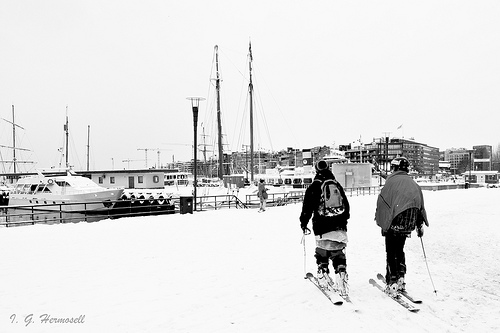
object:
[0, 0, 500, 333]
photo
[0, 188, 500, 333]
snow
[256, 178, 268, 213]
woman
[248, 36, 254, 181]
pole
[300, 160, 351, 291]
person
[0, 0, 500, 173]
sky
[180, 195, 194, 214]
can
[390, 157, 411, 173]
helmet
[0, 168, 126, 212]
boat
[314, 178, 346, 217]
backpack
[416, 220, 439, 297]
ski pole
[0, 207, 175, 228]
water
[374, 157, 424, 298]
people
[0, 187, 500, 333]
ground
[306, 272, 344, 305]
ski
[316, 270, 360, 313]
ski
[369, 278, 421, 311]
ski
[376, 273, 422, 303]
ski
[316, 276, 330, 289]
foot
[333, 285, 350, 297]
foot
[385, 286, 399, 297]
foot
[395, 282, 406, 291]
foot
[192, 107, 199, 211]
light pole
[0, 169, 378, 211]
pier